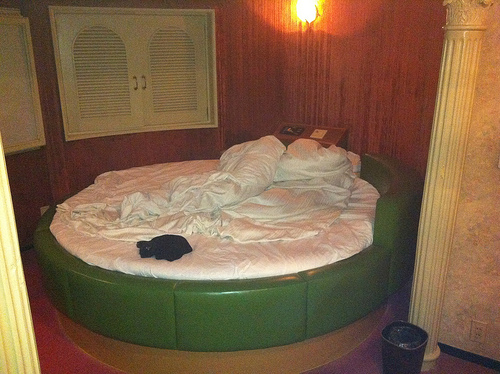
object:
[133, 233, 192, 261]
cat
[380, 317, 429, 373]
can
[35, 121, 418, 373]
bed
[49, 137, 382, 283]
blankets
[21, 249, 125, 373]
carpet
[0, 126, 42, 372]
column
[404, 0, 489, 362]
column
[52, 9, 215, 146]
shutters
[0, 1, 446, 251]
walls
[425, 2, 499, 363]
paper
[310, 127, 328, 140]
notebook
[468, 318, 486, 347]
socket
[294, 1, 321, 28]
light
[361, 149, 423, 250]
headboard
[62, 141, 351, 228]
pile